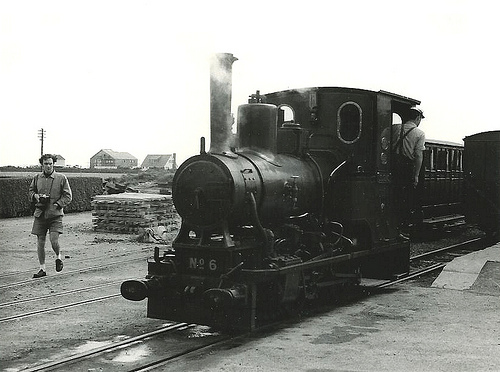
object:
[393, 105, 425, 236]
conductor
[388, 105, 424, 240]
person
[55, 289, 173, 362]
track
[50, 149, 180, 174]
building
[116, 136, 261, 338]
front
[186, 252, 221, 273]
word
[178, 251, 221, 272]
white letters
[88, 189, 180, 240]
wood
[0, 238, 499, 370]
tracks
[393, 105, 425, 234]
train conductor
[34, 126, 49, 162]
pole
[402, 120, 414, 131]
collar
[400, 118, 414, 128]
neck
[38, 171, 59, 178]
neck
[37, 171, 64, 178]
collar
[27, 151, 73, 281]
man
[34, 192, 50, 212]
camera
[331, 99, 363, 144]
train window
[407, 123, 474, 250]
passenger car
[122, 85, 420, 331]
engine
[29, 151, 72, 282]
man wearing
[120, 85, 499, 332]
train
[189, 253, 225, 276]
number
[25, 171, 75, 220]
coat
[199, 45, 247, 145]
steam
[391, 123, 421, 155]
suspenders